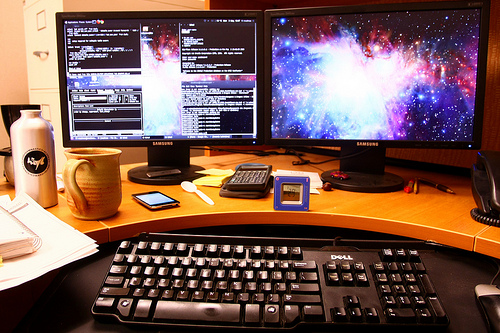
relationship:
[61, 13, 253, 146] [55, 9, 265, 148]
monitor have black frames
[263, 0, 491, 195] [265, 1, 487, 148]
monitors have black frames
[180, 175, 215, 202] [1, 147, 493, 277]
spoon on desk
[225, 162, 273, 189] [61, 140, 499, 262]
calculator on desk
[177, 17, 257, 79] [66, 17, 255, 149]
window with information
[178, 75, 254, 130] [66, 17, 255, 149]
window with information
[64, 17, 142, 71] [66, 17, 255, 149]
window with information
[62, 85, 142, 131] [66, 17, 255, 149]
window with information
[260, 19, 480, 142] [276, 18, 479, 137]
screen with picture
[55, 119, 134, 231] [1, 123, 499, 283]
mug sitting on desk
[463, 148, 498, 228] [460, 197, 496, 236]
phone with cord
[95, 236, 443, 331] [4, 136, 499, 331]
keyboard on desk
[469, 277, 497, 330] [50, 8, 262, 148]
mouse for computer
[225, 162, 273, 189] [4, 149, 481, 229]
calculator on desk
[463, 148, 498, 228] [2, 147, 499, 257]
phone on desk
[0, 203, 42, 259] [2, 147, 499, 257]
notebook on desk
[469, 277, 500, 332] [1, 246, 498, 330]
mouse on desk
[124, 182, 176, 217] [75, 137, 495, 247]
phone on desk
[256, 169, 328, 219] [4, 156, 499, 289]
cellphone on desk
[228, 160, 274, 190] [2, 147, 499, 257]
calculator on desk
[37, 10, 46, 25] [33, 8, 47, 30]
picture in frame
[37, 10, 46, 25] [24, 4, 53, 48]
picture on wall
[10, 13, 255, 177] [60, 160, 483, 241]
monitor on desk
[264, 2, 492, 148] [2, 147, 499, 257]
computer monitor on desk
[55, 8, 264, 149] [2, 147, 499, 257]
computer monitor on desk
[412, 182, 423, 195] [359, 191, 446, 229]
pencil on desk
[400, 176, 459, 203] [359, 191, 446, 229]
pens on desk